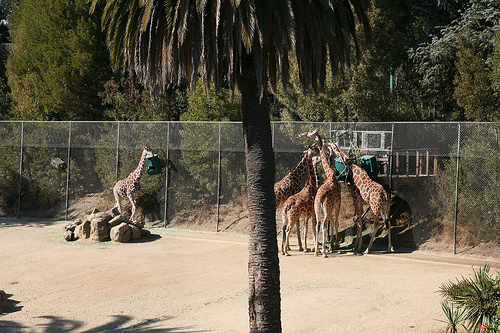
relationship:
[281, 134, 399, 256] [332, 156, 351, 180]
giraffes hanging around container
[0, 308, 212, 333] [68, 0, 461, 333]
shadow of tree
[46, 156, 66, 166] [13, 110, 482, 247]
video camera behind fence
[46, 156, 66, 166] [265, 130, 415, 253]
video camera pointed at giraffes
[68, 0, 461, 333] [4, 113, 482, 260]
tree behind fence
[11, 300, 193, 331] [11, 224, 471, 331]
shadow on ground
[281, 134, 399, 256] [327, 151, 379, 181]
giraffes eating from container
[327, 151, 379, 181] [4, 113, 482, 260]
container on fence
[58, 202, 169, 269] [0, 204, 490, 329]
rocks on ground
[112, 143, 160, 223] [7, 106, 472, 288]
animals near fence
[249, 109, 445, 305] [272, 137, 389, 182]
giraffe has necks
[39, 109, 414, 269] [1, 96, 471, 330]
animals in an area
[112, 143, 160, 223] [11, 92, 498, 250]
animals held in by fence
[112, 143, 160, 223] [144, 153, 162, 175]
animals eating out of a basket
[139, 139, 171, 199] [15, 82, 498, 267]
basket on fence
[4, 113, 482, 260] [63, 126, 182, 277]
fence next tro giraffe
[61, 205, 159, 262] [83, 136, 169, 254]
rocks next tro giraffe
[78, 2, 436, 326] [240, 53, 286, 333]
tree has a tree trunk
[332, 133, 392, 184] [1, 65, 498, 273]
bucket attached to fence